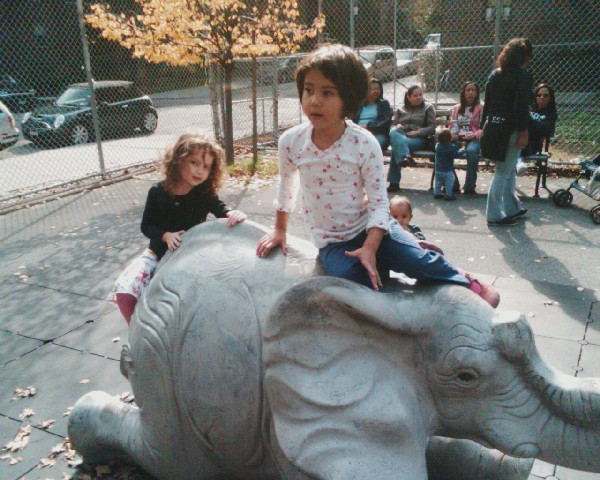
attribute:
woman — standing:
[524, 68, 554, 174]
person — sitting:
[362, 78, 390, 156]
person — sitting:
[379, 79, 435, 190]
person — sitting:
[522, 72, 563, 179]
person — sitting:
[449, 74, 488, 199]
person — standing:
[481, 33, 528, 219]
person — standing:
[450, 69, 484, 191]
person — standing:
[389, 73, 436, 191]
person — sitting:
[528, 78, 553, 164]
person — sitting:
[451, 72, 482, 193]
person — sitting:
[391, 77, 432, 184]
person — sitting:
[361, 72, 392, 154]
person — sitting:
[444, 78, 482, 197]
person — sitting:
[528, 72, 555, 154]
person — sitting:
[380, 84, 433, 192]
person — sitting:
[360, 77, 391, 149]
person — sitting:
[385, 80, 434, 189]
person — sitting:
[520, 78, 558, 166]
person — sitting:
[356, 73, 394, 136]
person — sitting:
[256, 40, 502, 309]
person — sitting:
[353, 77, 389, 153]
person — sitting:
[517, 78, 559, 158]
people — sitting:
[389, 80, 581, 195]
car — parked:
[13, 75, 162, 146]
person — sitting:
[387, 85, 436, 193]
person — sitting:
[439, 79, 484, 195]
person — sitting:
[522, 81, 555, 162]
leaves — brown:
[79, 5, 327, 68]